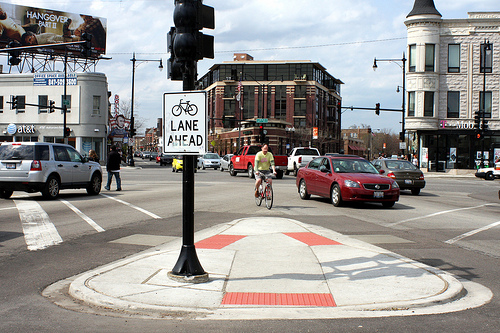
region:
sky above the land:
[278, 14, 373, 51]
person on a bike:
[238, 131, 297, 217]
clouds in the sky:
[242, 10, 332, 46]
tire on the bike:
[253, 183, 283, 212]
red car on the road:
[293, 153, 395, 214]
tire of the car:
[318, 183, 353, 211]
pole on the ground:
[125, 179, 240, 283]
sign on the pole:
[126, 74, 219, 189]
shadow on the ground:
[363, 253, 443, 314]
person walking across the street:
[101, 130, 145, 203]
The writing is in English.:
[161, 92, 206, 154]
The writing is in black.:
[162, 92, 207, 156]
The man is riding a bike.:
[250, 143, 278, 205]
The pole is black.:
[181, 157, 191, 230]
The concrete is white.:
[241, 248, 301, 283]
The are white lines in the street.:
[18, 200, 148, 230]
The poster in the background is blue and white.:
[30, 73, 78, 84]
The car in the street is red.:
[300, 167, 392, 199]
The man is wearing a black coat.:
[106, 142, 122, 188]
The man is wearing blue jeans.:
[105, 141, 121, 189]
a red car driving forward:
[291, 151, 403, 218]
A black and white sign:
[148, 83, 223, 163]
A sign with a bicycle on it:
[157, 84, 208, 126]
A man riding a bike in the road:
[242, 140, 284, 212]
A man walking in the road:
[99, 138, 131, 200]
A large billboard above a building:
[3, 2, 125, 68]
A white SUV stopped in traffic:
[3, 138, 109, 207]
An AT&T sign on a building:
[4, 120, 43, 141]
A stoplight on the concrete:
[163, 4, 214, 294]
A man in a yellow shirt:
[248, 148, 278, 178]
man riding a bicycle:
[252, 143, 276, 210]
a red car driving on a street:
[296, 152, 400, 214]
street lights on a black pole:
[163, 1, 218, 85]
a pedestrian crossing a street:
[106, 145, 124, 193]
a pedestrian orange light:
[475, 130, 482, 140]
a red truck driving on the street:
[228, 144, 290, 176]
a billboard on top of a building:
[1, 0, 106, 60]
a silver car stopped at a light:
[0, 140, 101, 200]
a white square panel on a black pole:
[162, 91, 209, 152]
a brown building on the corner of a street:
[192, 61, 344, 156]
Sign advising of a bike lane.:
[156, 83, 212, 163]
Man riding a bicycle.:
[243, 138, 288, 209]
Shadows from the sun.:
[307, 250, 485, 287]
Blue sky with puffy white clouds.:
[267, 5, 386, 42]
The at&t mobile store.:
[2, 120, 47, 142]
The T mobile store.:
[428, 120, 480, 133]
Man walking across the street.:
[98, 136, 127, 194]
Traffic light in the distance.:
[365, 93, 387, 124]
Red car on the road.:
[293, 136, 403, 216]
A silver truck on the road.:
[1, 137, 105, 199]